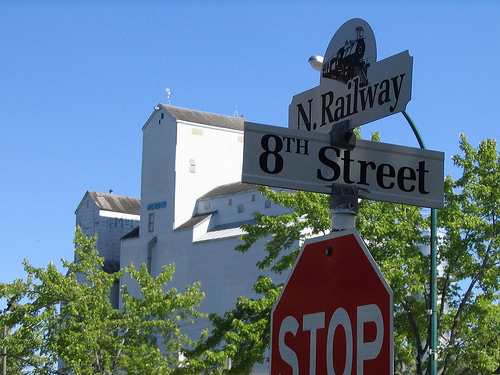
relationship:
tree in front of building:
[9, 134, 498, 364] [49, 83, 489, 374]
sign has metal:
[263, 231, 395, 374] [319, 230, 339, 264]